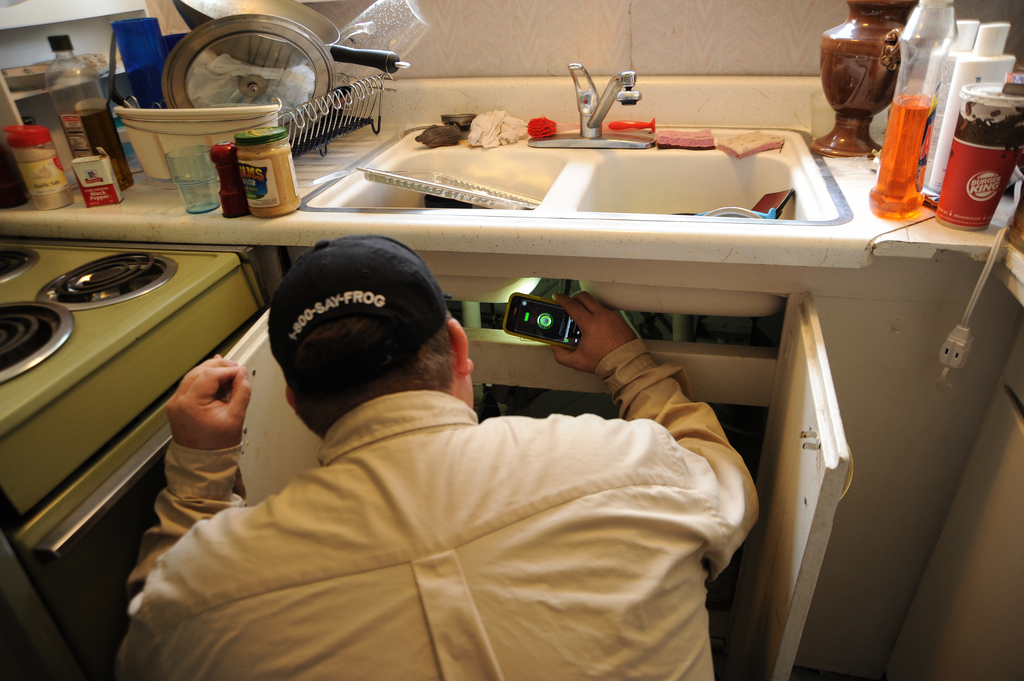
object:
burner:
[0, 244, 42, 287]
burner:
[33, 249, 182, 312]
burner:
[0, 300, 80, 384]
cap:
[264, 234, 451, 404]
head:
[264, 234, 479, 440]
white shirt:
[116, 335, 767, 681]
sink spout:
[614, 89, 643, 106]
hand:
[163, 353, 256, 452]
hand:
[550, 290, 640, 377]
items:
[47, 34, 138, 194]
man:
[115, 237, 761, 678]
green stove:
[0, 242, 276, 681]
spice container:
[0, 124, 76, 212]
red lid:
[3, 123, 53, 150]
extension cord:
[935, 224, 1014, 383]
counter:
[823, 134, 1024, 289]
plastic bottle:
[870, 0, 957, 223]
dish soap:
[868, 92, 936, 224]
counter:
[0, 114, 393, 249]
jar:
[233, 125, 303, 219]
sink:
[292, 123, 859, 231]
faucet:
[527, 61, 656, 149]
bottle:
[41, 30, 141, 190]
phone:
[500, 292, 583, 352]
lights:
[514, 298, 582, 348]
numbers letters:
[373, 294, 388, 308]